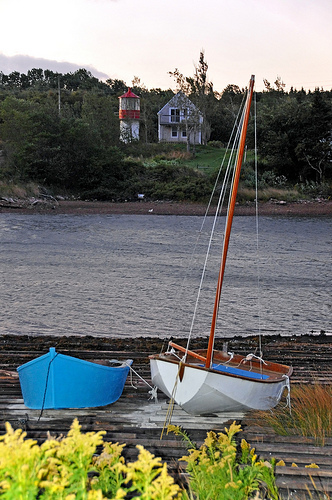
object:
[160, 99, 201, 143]
gray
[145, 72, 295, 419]
boat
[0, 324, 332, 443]
dock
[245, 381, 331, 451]
weeds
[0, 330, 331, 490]
boards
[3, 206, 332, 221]
shoreline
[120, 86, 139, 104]
red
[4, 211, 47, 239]
ripples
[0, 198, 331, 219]
shore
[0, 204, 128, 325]
blue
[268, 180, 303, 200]
grass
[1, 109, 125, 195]
shrubbery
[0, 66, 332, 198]
forest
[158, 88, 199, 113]
roof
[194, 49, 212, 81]
green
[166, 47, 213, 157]
trees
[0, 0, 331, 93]
white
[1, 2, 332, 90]
sky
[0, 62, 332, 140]
hill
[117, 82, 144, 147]
house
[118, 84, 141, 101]
top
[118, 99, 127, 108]
windows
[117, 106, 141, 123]
fence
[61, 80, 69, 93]
light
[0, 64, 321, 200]
back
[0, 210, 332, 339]
lake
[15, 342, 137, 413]
rafts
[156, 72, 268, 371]
large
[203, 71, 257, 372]
pole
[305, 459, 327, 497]
flower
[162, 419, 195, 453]
tip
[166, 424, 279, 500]
plant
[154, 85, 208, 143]
building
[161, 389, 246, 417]
bottom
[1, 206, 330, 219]
edge